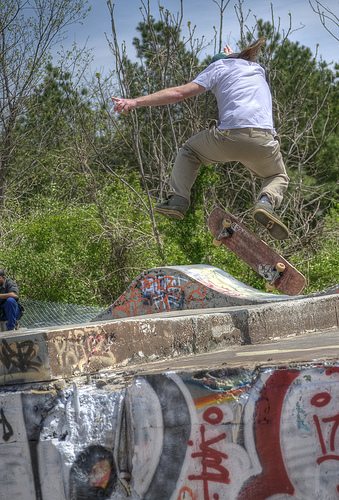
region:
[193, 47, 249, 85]
person has brown hair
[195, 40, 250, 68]
person has green cap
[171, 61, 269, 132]
person has grey shirt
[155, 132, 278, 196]
person has tan pants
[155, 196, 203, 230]
grey and tan shoes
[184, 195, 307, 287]
skateboard flips in air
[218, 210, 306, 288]
skateboard has tan wheels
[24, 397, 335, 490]
multicolor graffiti on wall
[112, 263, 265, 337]
ramp is behind skater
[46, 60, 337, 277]
green trees behind skater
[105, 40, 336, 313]
a man jumping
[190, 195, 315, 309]
a skateboard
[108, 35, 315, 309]
a man doing a trick on a skateboard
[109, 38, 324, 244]
a man jumping off the ground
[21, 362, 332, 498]
graffiti on the wall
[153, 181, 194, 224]
the shoe of the man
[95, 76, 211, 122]
the arm of the man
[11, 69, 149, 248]
trees and branches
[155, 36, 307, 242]
the man is wearing a purple shirt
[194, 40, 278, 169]
the man has a green cap on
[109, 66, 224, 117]
arm of a person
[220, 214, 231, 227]
wheel on a skateboard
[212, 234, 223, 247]
wheel on a skateboard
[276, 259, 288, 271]
wheel on a skateboard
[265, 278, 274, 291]
wheel on a skateboard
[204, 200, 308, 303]
skateboard in the air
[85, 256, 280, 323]
concrete ramp for skateboarding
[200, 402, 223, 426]
red letter painted in spray paint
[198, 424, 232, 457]
red letter painted in spray paint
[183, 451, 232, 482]
red letter painted in spray paint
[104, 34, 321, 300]
a man jumping a skateboard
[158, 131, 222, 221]
the leg of a man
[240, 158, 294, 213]
the leg of a man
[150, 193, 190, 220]
the foot of a man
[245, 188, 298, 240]
the foot of a man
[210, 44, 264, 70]
the head of a man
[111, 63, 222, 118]
the arm of a man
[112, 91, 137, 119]
the hand of a man